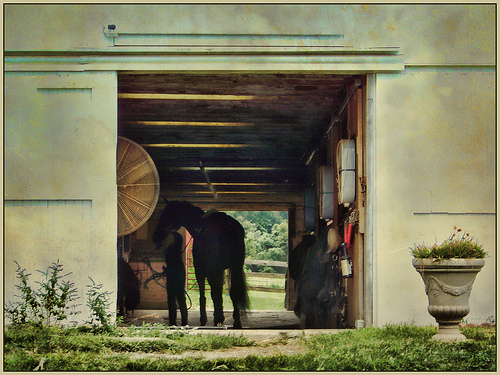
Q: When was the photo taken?
A: Daytime.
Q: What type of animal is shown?
A: Horse.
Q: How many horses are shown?
A: One.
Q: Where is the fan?
A: On the door.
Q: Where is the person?
A: Beside the horse.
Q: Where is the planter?
A: Beside the door.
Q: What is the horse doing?
A: Standing.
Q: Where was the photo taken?
A: At a barn.